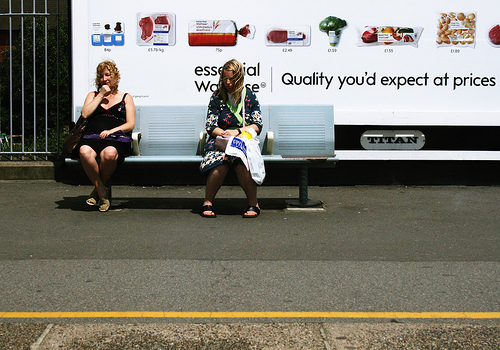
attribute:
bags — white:
[238, 126, 270, 183]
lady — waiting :
[191, 66, 271, 220]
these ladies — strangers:
[68, 54, 268, 220]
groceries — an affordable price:
[86, 2, 480, 56]